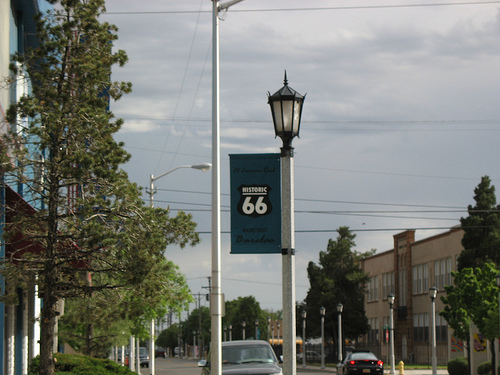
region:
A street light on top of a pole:
[254, 67, 316, 152]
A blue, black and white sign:
[224, 146, 298, 268]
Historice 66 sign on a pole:
[220, 150, 302, 258]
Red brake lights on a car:
[345, 354, 388, 371]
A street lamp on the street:
[421, 284, 448, 374]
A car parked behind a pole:
[195, 332, 292, 372]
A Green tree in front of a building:
[443, 170, 498, 373]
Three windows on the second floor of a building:
[407, 255, 432, 302]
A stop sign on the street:
[380, 327, 394, 347]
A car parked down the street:
[117, 343, 156, 372]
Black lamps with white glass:
[265, 68, 307, 153]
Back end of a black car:
[337, 348, 385, 372]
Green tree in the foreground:
[9, 0, 197, 370]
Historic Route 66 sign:
[228, 152, 283, 252]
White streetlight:
[141, 155, 212, 372]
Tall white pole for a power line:
[202, 0, 242, 371]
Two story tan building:
[354, 230, 499, 367]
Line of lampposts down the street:
[170, 284, 495, 371]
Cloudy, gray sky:
[94, 2, 499, 300]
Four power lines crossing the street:
[116, 189, 496, 241]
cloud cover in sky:
[105, 2, 498, 312]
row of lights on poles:
[178, 286, 443, 366]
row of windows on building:
[360, 257, 455, 306]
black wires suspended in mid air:
[135, 191, 496, 242]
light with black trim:
[269, 71, 306, 143]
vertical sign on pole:
[229, 149, 293, 257]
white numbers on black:
[241, 194, 267, 216]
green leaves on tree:
[440, 263, 497, 338]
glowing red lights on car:
[338, 348, 383, 373]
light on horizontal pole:
[148, 159, 214, 185]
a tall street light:
[385, 291, 397, 372]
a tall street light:
[425, 285, 440, 372]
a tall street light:
[335, 301, 345, 367]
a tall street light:
[318, 305, 329, 368]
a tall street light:
[299, 308, 311, 368]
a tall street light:
[267, 68, 308, 372]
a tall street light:
[253, 316, 260, 337]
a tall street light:
[240, 318, 245, 339]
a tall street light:
[227, 320, 232, 338]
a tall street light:
[147, 160, 214, 208]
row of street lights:
[175, 281, 478, 366]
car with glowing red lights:
[341, 350, 386, 372]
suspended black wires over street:
[155, 184, 439, 241]